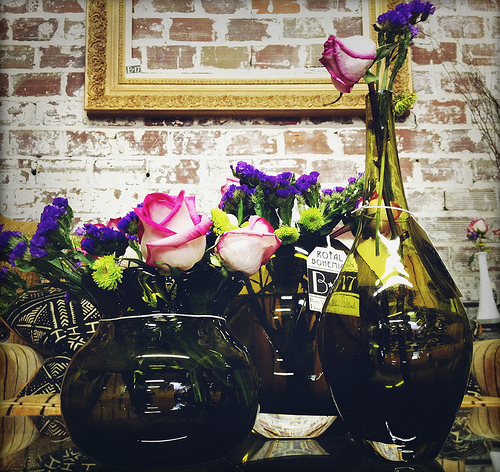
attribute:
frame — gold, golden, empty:
[84, 0, 411, 116]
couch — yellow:
[447, 334, 499, 448]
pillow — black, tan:
[1, 288, 103, 399]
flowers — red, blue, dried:
[322, 0, 433, 94]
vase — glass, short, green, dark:
[60, 310, 255, 470]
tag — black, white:
[306, 244, 358, 317]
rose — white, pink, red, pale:
[134, 189, 212, 271]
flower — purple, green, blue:
[221, 162, 269, 204]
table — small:
[0, 411, 498, 468]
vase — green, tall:
[313, 91, 474, 467]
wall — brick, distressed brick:
[2, 0, 499, 301]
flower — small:
[91, 255, 121, 290]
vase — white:
[473, 252, 494, 322]